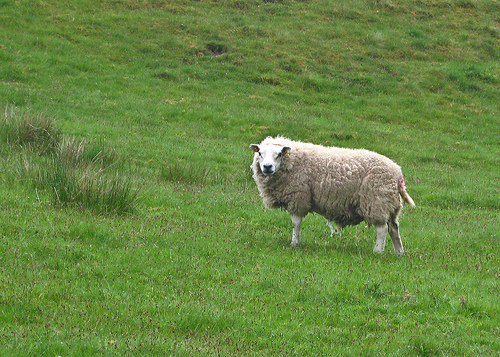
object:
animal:
[249, 133, 416, 255]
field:
[0, 0, 500, 357]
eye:
[276, 156, 279, 161]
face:
[258, 150, 283, 174]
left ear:
[280, 146, 291, 158]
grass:
[1, 0, 500, 357]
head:
[249, 143, 291, 176]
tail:
[398, 171, 416, 209]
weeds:
[0, 99, 157, 213]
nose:
[263, 164, 273, 172]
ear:
[249, 143, 260, 152]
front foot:
[290, 240, 301, 248]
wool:
[250, 135, 416, 228]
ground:
[1, 1, 500, 357]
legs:
[363, 210, 404, 251]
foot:
[373, 245, 385, 254]